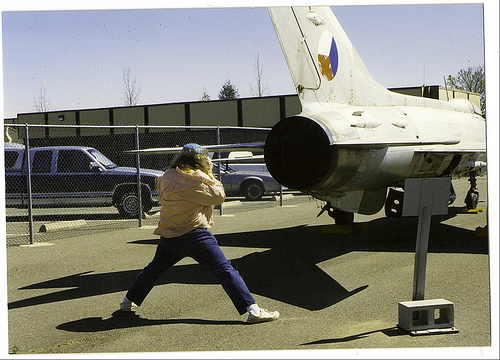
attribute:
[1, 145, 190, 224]
truck — pickup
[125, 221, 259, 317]
pants — blue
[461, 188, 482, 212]
airplane wheel — down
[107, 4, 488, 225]
plane — small, white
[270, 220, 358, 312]
shadow — on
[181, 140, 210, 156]
hat — on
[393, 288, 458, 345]
concrete block — cinder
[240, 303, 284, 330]
white shoes — on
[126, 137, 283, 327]
person — with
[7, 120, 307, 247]
fence — chain link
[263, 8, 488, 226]
jet — grey, single-engine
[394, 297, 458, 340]
block — is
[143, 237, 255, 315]
pants — are